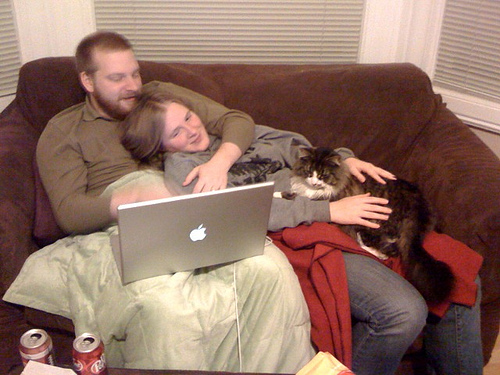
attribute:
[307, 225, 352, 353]
blanket — red 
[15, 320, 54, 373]
soda can — brown , football 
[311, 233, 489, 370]
pants — blue 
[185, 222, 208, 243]
logo — white 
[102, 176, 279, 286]
laptop — silver 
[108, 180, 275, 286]
computer — gray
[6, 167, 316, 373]
blanket — white 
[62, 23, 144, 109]
hair — brown , short 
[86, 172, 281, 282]
laptop — silver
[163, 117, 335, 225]
sweatshirt — gray 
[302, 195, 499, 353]
jeans — blue 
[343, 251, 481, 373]
jeans — blue 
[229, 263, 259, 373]
white cable — White 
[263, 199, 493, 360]
blanket — red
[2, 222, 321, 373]
blanket — white 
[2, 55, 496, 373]
couch — brown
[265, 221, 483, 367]
blanket — white , red 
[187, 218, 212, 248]
logo — Apple 